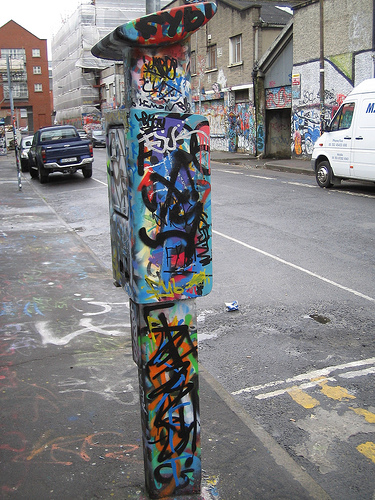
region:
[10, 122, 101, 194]
two cars parked on the side of the road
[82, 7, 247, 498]
graffiti on the pole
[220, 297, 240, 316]
trash on the ground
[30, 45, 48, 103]
row of three windows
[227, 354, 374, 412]
white lines on the ground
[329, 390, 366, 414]
yellow paint is peeling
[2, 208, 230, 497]
graffiti on the ground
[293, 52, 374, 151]
graffiti on the side of the building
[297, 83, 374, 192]
white van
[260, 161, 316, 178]
curb on the side of the road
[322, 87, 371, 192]
this is a car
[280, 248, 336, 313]
a line on the road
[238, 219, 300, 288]
a line on the road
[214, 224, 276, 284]
a line on the road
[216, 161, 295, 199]
a line on the road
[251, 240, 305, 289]
a line on the road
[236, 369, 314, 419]
a line on the road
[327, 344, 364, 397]
a line on the road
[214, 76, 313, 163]
graffiti on the wall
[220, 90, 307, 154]
graffiti on the wall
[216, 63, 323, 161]
graffiti on the wall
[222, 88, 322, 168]
graffiti on the wall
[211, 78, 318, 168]
graffiti on the wall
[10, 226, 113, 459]
graffiti on the sidewalk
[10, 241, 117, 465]
graffiti on the sidewalk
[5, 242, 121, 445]
graffiti on the sidewalk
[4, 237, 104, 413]
graffiti on the sidewalk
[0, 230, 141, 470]
graffiti on the sidewalk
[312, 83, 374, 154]
this is a van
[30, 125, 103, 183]
this is a pickup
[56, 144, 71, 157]
the pickup is blue in color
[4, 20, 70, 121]
this is a building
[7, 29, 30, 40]
the wall is brown in color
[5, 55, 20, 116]
this is a pole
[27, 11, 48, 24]
this is the sky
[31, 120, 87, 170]
this is a pickup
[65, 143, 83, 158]
the pickup is blue in color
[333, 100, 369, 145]
this is a van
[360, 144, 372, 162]
the van is white in color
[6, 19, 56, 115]
this is a building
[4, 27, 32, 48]
this is the wall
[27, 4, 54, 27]
this is the sky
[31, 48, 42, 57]
this is the window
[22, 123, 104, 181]
Truck on the curb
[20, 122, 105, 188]
Blue truck parked near sidewalk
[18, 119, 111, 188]
Truck parked near sidewalk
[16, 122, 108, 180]
Blue truck parked in street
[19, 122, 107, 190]
Truck parked in street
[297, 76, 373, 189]
White van parked on curb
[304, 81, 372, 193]
White van parked near sidewalk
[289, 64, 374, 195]
Van parked near sidewalk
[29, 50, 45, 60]
a window on the building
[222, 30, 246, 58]
a window on the building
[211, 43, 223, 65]
a window on the building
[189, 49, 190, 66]
a window on the building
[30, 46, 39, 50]
a window on the building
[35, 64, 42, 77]
a window on the building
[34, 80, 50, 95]
a window on the building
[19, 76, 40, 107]
a window on the building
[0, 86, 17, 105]
a window on the building